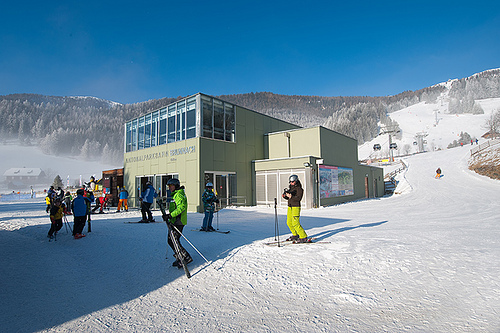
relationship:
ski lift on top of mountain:
[365, 108, 486, 167] [1, 67, 500, 211]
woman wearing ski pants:
[270, 173, 313, 245] [284, 204, 309, 238]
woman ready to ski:
[270, 173, 313, 245] [269, 234, 329, 247]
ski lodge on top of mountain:
[93, 92, 384, 201] [1, 67, 500, 211]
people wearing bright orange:
[432, 167, 442, 181] [436, 172, 443, 179]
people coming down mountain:
[432, 167, 442, 181] [1, 67, 500, 211]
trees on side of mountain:
[6, 67, 497, 156] [1, 67, 500, 211]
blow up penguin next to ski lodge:
[85, 173, 99, 189] [93, 92, 384, 201]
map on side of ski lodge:
[318, 164, 357, 200] [93, 92, 384, 201]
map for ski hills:
[318, 164, 357, 200] [364, 68, 496, 197]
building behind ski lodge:
[4, 167, 48, 188] [93, 92, 384, 201]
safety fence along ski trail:
[471, 135, 497, 159] [397, 135, 495, 206]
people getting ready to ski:
[160, 178, 193, 268] [155, 203, 209, 279]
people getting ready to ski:
[132, 181, 161, 227] [132, 196, 158, 227]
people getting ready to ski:
[45, 192, 70, 240] [43, 213, 76, 245]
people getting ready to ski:
[200, 181, 221, 232] [200, 204, 232, 238]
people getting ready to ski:
[70, 188, 94, 240] [72, 200, 94, 241]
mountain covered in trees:
[1, 67, 500, 211] [6, 67, 497, 156]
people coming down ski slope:
[432, 165, 445, 182] [397, 135, 495, 206]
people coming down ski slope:
[474, 138, 479, 146] [397, 135, 495, 206]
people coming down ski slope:
[470, 140, 473, 147] [397, 135, 495, 206]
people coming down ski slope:
[459, 142, 465, 148] [397, 135, 495, 206]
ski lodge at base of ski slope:
[93, 92, 384, 201] [397, 135, 495, 206]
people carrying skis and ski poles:
[160, 178, 193, 268] [155, 203, 209, 279]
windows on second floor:
[124, 91, 236, 155] [124, 101, 365, 158]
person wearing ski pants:
[270, 173, 313, 245] [284, 204, 309, 238]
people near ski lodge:
[48, 175, 314, 280] [93, 92, 384, 201]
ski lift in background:
[365, 108, 486, 167] [364, 68, 496, 197]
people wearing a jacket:
[160, 178, 193, 268] [164, 179, 189, 231]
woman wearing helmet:
[270, 173, 313, 245] [285, 172, 301, 185]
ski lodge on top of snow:
[93, 92, 384, 201] [10, 102, 496, 330]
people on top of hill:
[432, 167, 442, 181] [397, 135, 495, 206]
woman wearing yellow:
[270, 173, 313, 245] [284, 204, 309, 238]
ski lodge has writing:
[93, 92, 384, 201] [123, 145, 201, 165]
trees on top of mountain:
[6, 67, 497, 156] [1, 67, 500, 211]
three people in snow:
[455, 135, 487, 150] [10, 102, 496, 330]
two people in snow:
[166, 175, 231, 276] [10, 102, 496, 330]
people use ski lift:
[48, 175, 314, 280] [365, 108, 486, 167]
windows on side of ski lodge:
[124, 91, 236, 155] [93, 92, 384, 201]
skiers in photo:
[48, 175, 314, 280] [9, 3, 498, 331]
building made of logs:
[4, 167, 48, 188] [5, 176, 40, 187]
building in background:
[4, 167, 48, 188] [3, 95, 123, 210]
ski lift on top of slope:
[365, 108, 486, 167] [364, 68, 496, 197]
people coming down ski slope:
[432, 167, 442, 181] [397, 135, 495, 206]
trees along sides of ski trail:
[6, 67, 497, 156] [397, 135, 495, 206]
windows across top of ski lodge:
[124, 91, 236, 155] [93, 92, 384, 201]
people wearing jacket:
[160, 178, 193, 268] [164, 179, 189, 231]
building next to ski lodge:
[4, 167, 48, 188] [93, 92, 384, 201]